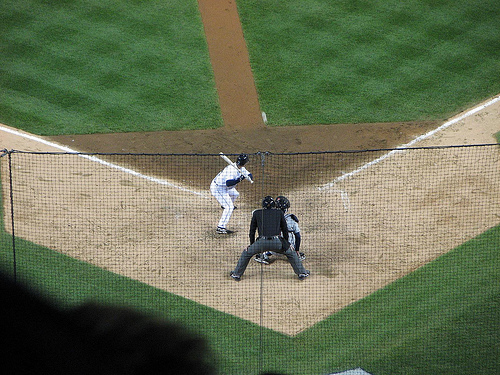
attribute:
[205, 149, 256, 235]
baseball player — batting, watching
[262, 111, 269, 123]
baseball — white, small, blurry, moving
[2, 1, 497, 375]
grass — mowed, green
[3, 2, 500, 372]
baseball field — green, large, active, dark, brown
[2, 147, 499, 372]
net — large, black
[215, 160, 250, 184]
shirt — white, light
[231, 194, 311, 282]
umpire — kneeling, crouching, bending, standing, black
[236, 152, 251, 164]
helmet — black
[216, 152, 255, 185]
bat — white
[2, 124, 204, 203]
line — white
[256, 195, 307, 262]
catcher — ready, kneeling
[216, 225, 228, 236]
shoe — black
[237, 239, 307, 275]
pants — grey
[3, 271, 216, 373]
hair — spectator's